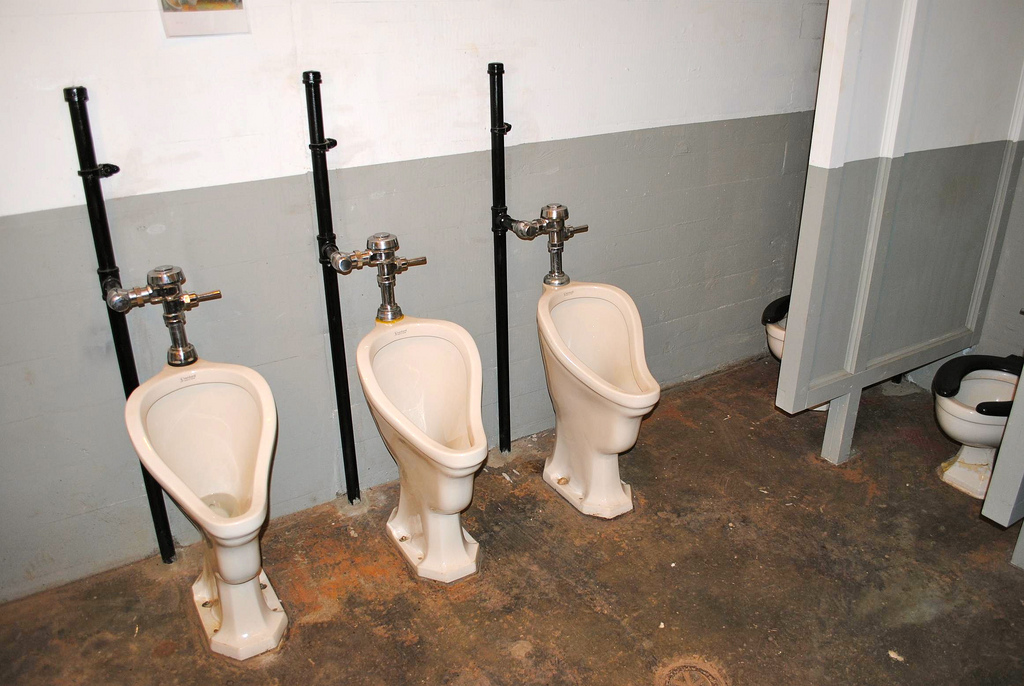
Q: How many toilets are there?
A: Two.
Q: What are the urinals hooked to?
A: Black pipes on the wall.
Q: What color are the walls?
A: Gray and white.